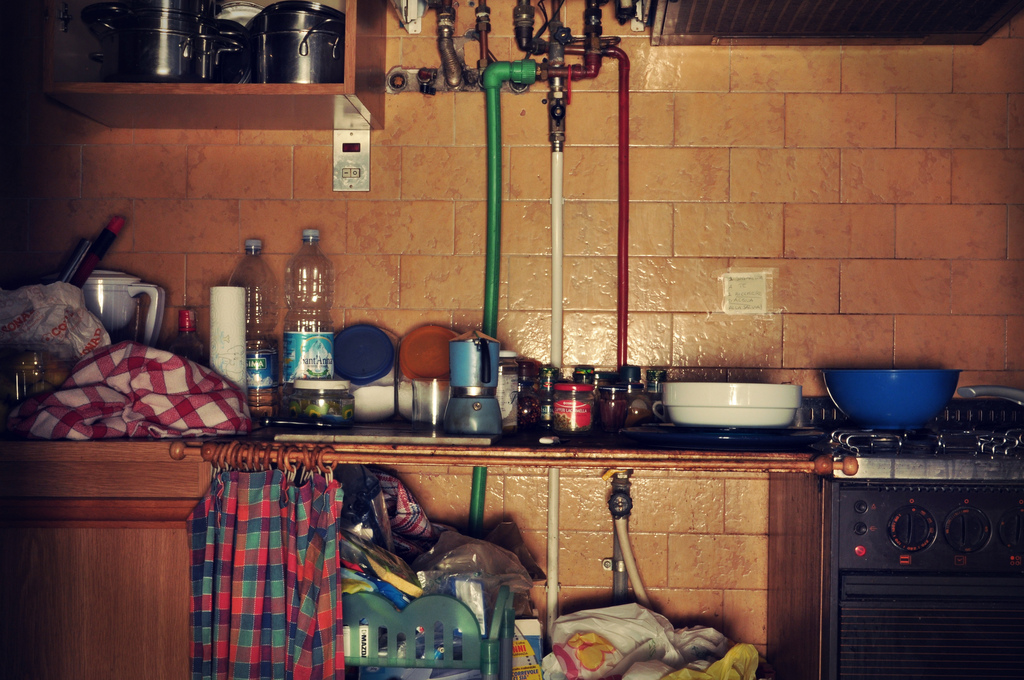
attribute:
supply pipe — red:
[609, 52, 646, 372]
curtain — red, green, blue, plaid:
[184, 443, 359, 677]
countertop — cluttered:
[17, 395, 839, 517]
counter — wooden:
[203, 429, 876, 507]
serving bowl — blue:
[832, 358, 958, 439]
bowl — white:
[661, 373, 806, 432]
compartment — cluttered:
[341, 488, 758, 677]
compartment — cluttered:
[322, 458, 776, 670]